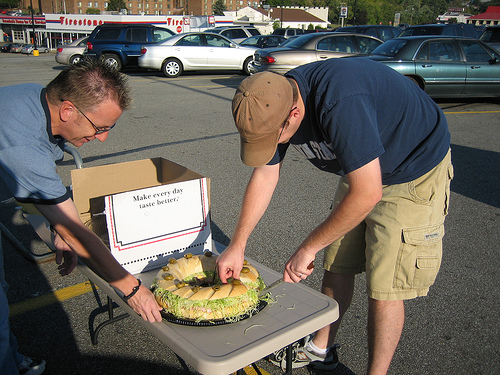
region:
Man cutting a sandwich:
[197, 45, 469, 370]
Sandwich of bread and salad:
[136, 235, 276, 337]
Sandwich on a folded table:
[121, 220, 343, 370]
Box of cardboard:
[56, 140, 231, 290]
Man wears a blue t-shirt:
[201, 29, 470, 374]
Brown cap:
[220, 57, 306, 174]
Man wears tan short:
[211, 41, 481, 372]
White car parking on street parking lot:
[123, 21, 272, 84]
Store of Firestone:
[46, 9, 221, 41]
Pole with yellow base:
[18, 1, 45, 58]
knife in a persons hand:
[251, 256, 329, 306]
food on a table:
[140, 242, 282, 338]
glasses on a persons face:
[53, 91, 122, 150]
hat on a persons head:
[220, 63, 302, 176]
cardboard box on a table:
[66, 148, 221, 280]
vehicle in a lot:
[132, 21, 272, 87]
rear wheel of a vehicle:
[156, 53, 188, 81]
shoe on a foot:
[257, 328, 343, 373]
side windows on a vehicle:
[409, 33, 499, 74]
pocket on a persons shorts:
[385, 218, 456, 300]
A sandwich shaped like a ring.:
[140, 226, 270, 327]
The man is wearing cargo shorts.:
[201, 45, 446, 291]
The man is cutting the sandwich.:
[151, 50, 476, 365]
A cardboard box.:
[67, 155, 229, 275]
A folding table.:
[0, 200, 375, 365]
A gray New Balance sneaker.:
[250, 315, 352, 370]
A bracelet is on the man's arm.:
[105, 260, 160, 315]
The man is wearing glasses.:
[45, 65, 126, 160]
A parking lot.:
[30, 0, 495, 120]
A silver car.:
[133, 25, 261, 85]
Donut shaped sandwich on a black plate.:
[147, 252, 268, 327]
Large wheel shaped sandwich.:
[152, 247, 259, 324]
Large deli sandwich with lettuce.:
[50, 250, 340, 372]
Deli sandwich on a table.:
[47, 240, 340, 373]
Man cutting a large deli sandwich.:
[142, 56, 455, 373]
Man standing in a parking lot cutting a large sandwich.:
[153, 54, 455, 371]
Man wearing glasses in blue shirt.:
[1, 48, 266, 373]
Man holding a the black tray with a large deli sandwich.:
[1, 54, 262, 374]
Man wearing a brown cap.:
[197, 55, 452, 373]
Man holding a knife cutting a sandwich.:
[146, 56, 454, 373]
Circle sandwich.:
[144, 220, 318, 345]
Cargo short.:
[317, 165, 496, 358]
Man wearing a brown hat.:
[228, 65, 379, 240]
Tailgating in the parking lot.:
[13, 57, 401, 366]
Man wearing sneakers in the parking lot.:
[257, 323, 357, 368]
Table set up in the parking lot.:
[30, 208, 285, 363]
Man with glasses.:
[43, 70, 187, 171]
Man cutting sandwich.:
[127, 228, 364, 348]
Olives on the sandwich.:
[150, 197, 237, 352]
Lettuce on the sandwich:
[170, 270, 259, 344]